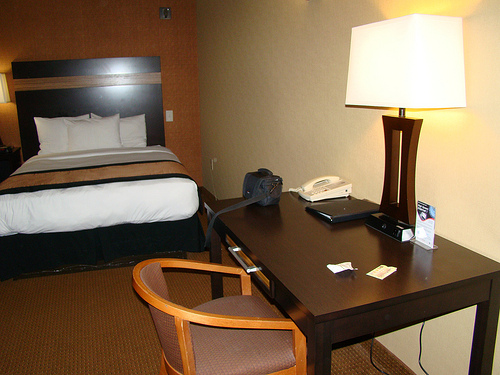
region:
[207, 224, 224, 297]
the leg of a brown table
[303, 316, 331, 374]
the leg of a brown table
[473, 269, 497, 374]
the leg of a brown table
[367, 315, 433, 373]
a black cord hanging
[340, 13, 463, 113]
a white lampshade on a lamp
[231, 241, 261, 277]
the silver handle of a drawer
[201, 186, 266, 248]
the black handle of a bag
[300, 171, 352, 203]
the white phone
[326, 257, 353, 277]
a small piece of paper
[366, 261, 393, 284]
a small piece of paper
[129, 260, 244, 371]
Wooden and fabric chair.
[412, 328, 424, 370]
Black cord hanging down.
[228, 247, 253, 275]
Silver handle on desk drawer.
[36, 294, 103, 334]
Flat brown pattern carpet.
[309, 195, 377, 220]
Black informational notebook on desk.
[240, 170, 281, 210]
Black video camera case.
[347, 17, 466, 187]
Table lamp illuminating the room.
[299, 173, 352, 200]
Telephone on office desk.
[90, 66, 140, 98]
Light reflecting on headboard.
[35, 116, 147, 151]
Three fluffy white pillows.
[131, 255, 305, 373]
the wooden rounded back chair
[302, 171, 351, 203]
the white corded phone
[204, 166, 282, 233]
the black camera bag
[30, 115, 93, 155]
the white pillow on the bed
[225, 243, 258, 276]
the silver handle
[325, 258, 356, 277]
the small piece of paper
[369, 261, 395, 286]
the piece of paper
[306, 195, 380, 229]
the black folder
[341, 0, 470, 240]
a lamp sitting on a table.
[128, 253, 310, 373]
a brown chair.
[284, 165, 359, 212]
a phone on a table.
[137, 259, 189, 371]
the back of a seat.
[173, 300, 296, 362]
a pink seat cushion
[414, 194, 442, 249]
a display on a table.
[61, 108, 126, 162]
a pillow on a bed.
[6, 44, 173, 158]
a large wooden head board.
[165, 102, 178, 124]
a light switch on a wall.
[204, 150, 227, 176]
a power outlet.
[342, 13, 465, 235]
lamp on a table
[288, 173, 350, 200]
a telephone on the table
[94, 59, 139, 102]
reflection of a light on the headboard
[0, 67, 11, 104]
a lamp on the nightstand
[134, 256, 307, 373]
a mismatched chair under the table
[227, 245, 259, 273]
the metal handle of a drawer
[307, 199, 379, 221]
the notebook on the table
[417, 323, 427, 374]
an electrical cord near the wall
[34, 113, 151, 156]
pillows stacked on the bed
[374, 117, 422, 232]
wooden base of the lamp